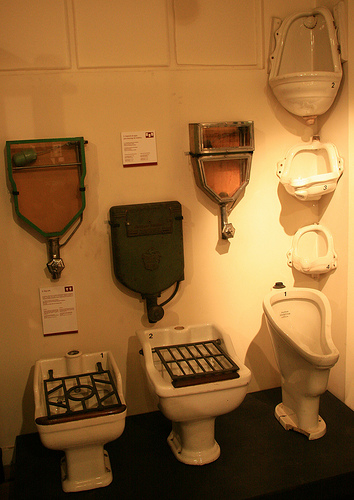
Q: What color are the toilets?
A: White.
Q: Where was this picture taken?
A: A bathroom museum.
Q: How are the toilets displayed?
A: Against a wall.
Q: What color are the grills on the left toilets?
A: Black.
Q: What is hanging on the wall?
A: Flushing mechanisms.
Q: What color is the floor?
A: Black.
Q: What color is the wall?
A: White.